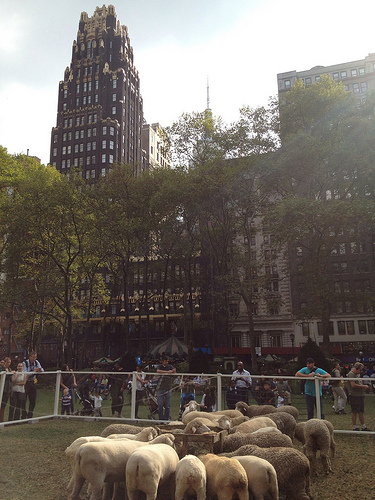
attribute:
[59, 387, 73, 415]
child — small, blond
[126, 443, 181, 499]
sheep — feeding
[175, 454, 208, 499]
sheep — feeding, off white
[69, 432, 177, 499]
sheep — feeding, off white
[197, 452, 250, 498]
sheep — feeding, off white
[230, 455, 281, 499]
sheep — feeding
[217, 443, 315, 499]
sheep — feeding, off white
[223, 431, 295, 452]
sheep — feeding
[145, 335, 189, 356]
awning — blue, white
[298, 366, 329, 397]
shirt — blue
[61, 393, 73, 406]
shirt — striped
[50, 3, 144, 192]
building — old, beautiful, black, gold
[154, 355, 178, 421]
person — watching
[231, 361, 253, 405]
person — watching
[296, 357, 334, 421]
person — watching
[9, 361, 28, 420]
person — watching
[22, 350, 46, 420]
person — watching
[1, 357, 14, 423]
person — watching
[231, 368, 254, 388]
shirt — white